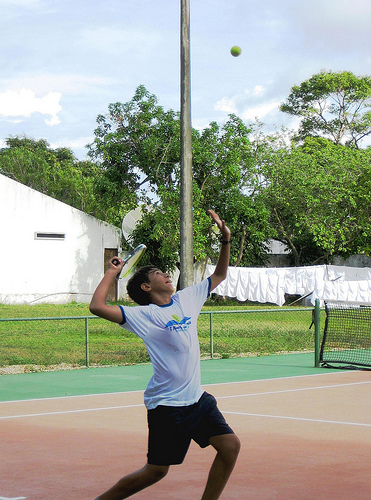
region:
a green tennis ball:
[227, 43, 242, 58]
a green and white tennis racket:
[110, 243, 146, 280]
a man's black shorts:
[135, 390, 233, 467]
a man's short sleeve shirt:
[110, 276, 239, 409]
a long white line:
[218, 403, 367, 434]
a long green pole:
[216, 299, 312, 319]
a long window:
[35, 230, 68, 241]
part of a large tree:
[277, 62, 369, 150]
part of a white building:
[1, 175, 120, 310]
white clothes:
[193, 260, 368, 308]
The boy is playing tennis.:
[98, 231, 253, 492]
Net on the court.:
[318, 296, 359, 378]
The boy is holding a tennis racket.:
[97, 232, 152, 282]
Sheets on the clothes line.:
[217, 260, 343, 303]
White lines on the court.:
[238, 382, 366, 457]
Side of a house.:
[13, 193, 135, 306]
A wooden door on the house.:
[94, 235, 126, 307]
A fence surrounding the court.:
[27, 309, 326, 353]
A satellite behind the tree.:
[116, 194, 158, 254]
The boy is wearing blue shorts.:
[124, 384, 251, 462]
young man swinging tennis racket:
[74, 199, 288, 498]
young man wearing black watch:
[84, 199, 253, 497]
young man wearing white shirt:
[72, 195, 249, 497]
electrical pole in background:
[128, 0, 215, 308]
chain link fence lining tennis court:
[0, 304, 313, 369]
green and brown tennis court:
[1, 355, 370, 497]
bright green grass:
[1, 293, 369, 371]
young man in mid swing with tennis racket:
[51, 191, 316, 498]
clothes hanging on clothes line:
[166, 238, 367, 390]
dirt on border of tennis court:
[1, 344, 368, 374]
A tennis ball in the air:
[216, 39, 260, 74]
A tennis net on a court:
[305, 296, 369, 368]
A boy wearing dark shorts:
[129, 388, 249, 475]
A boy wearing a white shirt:
[115, 277, 235, 419]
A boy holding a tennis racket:
[106, 238, 152, 294]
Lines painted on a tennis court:
[236, 368, 305, 405]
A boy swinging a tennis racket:
[92, 197, 252, 437]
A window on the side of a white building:
[32, 226, 68, 247]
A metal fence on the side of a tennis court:
[241, 306, 303, 358]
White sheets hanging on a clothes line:
[243, 264, 309, 311]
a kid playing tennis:
[81, 217, 256, 474]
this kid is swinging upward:
[79, 207, 247, 341]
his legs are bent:
[96, 384, 258, 499]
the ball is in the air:
[158, 23, 278, 86]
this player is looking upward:
[117, 258, 185, 323]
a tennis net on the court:
[289, 281, 370, 380]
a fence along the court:
[9, 300, 307, 365]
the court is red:
[13, 391, 356, 490]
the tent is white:
[209, 247, 369, 309]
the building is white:
[2, 169, 128, 310]